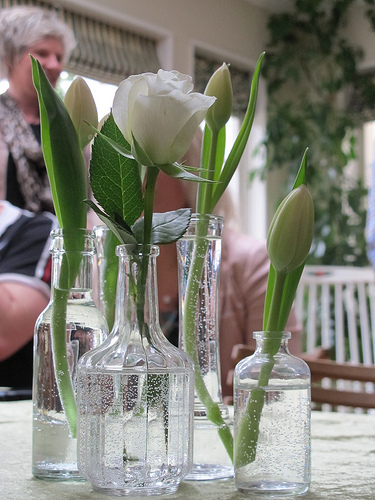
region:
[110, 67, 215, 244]
A white flower.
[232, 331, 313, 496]
A small clear jar.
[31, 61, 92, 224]
A long green leaf.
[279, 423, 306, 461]
Bubbles in the jar.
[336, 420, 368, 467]
Part of the table.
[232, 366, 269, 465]
The stem of the flower.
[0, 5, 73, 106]
The head of a woman.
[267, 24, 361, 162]
A plant in the background.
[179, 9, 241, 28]
part of the white wall.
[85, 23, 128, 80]
Part of the striped curtain.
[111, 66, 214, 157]
white bud of a rose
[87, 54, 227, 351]
rose in a clear vase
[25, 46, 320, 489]
clear vases with budded roses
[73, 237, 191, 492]
clear vase with a rose inside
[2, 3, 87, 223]
gray haired woman in the background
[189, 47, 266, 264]
window in a room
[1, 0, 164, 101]
large window in a room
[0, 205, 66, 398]
left shoulder of a person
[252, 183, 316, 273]
flower that hasn't bloomed yet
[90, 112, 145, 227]
leaf of a rose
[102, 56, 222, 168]
White rose in a vase.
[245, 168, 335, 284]
Unopened bud in a vase.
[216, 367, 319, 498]
Water in a vase.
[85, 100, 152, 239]
Green leaf next to the rose.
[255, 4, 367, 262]
Greenery climbing the wall.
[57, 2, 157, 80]
Blinds at the top of the window.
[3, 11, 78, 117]
Head of a woman.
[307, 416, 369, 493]
Table where the flowers are sitting.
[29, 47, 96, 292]
Tall leaf in a vase.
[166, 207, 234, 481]
A very tall vase.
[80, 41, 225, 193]
white flower in front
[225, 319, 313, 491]
small glass jar on table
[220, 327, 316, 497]
small glass vase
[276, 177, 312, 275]
small green plant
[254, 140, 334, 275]
flower not yet bloomed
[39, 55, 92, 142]
leaf in flower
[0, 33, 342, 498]
flowers sitting on table in glass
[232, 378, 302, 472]
small bubbles in the jar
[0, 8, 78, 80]
head of woman in background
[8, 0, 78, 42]
white and grey hair on head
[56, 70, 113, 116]
glowing sunlight through window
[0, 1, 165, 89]
striped blinds on window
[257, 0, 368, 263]
green leaves of plant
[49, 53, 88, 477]
green leaf in water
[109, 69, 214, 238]
white flower on green stem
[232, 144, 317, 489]
flower bud in bottle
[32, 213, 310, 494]
four bottles of water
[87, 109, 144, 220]
green leaf with veins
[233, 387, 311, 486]
bubbles in stagnant water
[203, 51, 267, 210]
long green flower leaf